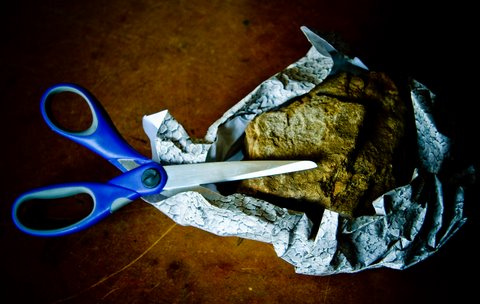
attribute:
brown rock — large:
[240, 63, 429, 215]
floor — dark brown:
[3, 3, 478, 297]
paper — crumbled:
[133, 22, 476, 277]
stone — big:
[222, 68, 434, 243]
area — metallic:
[99, 83, 334, 272]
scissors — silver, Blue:
[1, 76, 344, 259]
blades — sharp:
[162, 158, 318, 188]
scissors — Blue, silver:
[14, 79, 319, 235]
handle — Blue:
[29, 79, 158, 235]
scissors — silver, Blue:
[3, 110, 269, 212]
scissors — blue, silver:
[38, 82, 341, 280]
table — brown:
[1, 0, 479, 302]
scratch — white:
[78, 221, 196, 293]